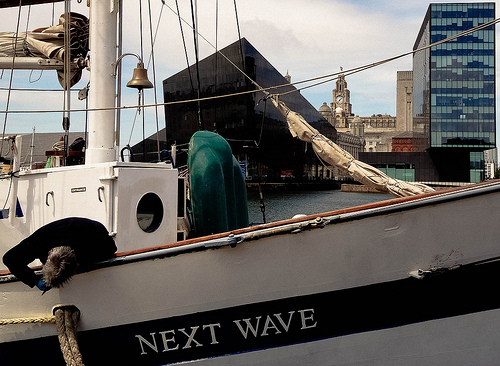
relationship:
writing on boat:
[133, 293, 324, 359] [3, 0, 500, 357]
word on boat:
[134, 317, 224, 358] [3, 0, 500, 357]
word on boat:
[232, 307, 325, 339] [3, 0, 500, 357]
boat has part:
[3, 0, 500, 357] [5, 3, 499, 357]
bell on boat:
[110, 47, 152, 101] [3, 0, 500, 357]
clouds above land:
[7, 3, 420, 112] [320, 62, 411, 150]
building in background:
[314, 65, 358, 137] [4, 4, 490, 172]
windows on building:
[338, 136, 367, 155] [332, 130, 368, 165]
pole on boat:
[88, 0, 125, 167] [3, 0, 500, 357]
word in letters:
[134, 317, 224, 358] [131, 319, 228, 355]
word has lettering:
[232, 307, 325, 339] [232, 301, 315, 344]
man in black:
[2, 214, 118, 296] [3, 217, 117, 290]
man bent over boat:
[2, 214, 118, 296] [3, 0, 500, 357]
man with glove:
[2, 214, 118, 296] [37, 280, 50, 291]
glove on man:
[37, 280, 50, 291] [2, 214, 118, 296]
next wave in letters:
[128, 300, 316, 357] [134, 297, 327, 357]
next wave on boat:
[128, 300, 316, 357] [3, 0, 500, 357]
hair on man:
[39, 241, 78, 290] [2, 214, 118, 296]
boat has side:
[3, 0, 500, 357] [2, 185, 499, 359]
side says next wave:
[2, 185, 499, 359] [128, 300, 316, 357]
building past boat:
[161, 35, 339, 149] [0, 0, 500, 366]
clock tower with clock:
[329, 66, 353, 128] [336, 93, 344, 104]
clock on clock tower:
[336, 93, 344, 104] [329, 66, 353, 128]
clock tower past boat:
[329, 66, 353, 128] [0, 0, 500, 366]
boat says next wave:
[3, 0, 500, 357] [128, 300, 316, 357]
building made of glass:
[161, 35, 339, 149] [163, 37, 341, 150]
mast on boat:
[284, 104, 434, 204] [3, 0, 500, 357]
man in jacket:
[2, 216, 118, 295] [2, 216, 123, 287]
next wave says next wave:
[132, 305, 317, 357] [135, 296, 321, 357]